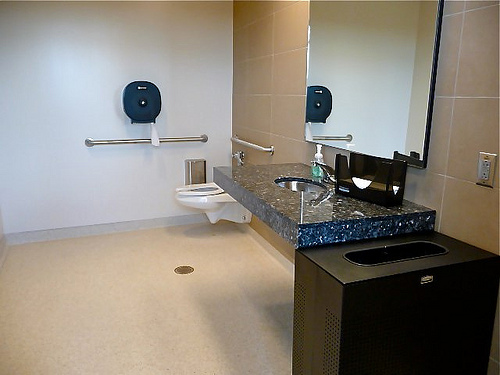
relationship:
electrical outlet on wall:
[476, 151, 499, 187] [16, 13, 131, 89]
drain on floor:
[173, 265, 196, 276] [1, 219, 295, 374]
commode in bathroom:
[174, 151, 254, 225] [2, 2, 482, 370]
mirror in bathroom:
[305, 1, 444, 168] [2, 2, 482, 370]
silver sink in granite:
[275, 180, 325, 192] [212, 165, 439, 245]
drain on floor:
[173, 265, 196, 276] [0, 223, 293, 375]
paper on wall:
[150, 122, 160, 147] [73, 56, 205, 141]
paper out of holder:
[149, 120, 159, 147] [123, 79, 163, 124]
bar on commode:
[99, 123, 283, 178] [155, 151, 280, 218]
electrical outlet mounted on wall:
[469, 147, 497, 194] [232, 2, 495, 368]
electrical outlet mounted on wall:
[469, 147, 497, 194] [5, 5, 238, 237]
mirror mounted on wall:
[305, 1, 444, 168] [231, 1, 498, 267]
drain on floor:
[170, 262, 200, 279] [70, 261, 160, 319]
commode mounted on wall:
[174, 151, 254, 225] [5, 5, 238, 237]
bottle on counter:
[307, 142, 332, 179] [207, 155, 437, 242]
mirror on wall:
[305, 1, 444, 168] [228, 5, 485, 290]